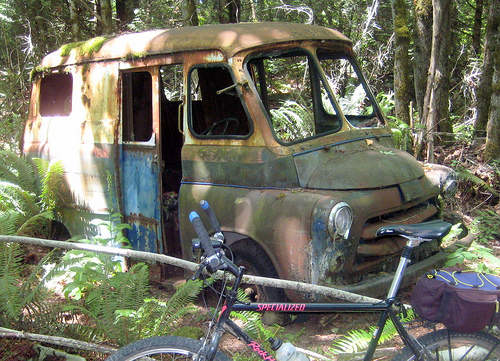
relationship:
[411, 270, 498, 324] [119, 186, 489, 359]
bag on back of bike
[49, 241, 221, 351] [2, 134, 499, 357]
plant on ground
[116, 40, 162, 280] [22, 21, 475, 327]
door on car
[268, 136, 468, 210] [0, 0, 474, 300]
hood on truck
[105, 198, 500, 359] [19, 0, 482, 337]
bicycle in front of truck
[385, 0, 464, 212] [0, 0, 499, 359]
tree in woods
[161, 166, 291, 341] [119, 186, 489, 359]
handle bars on bike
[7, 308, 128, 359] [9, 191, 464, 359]
branch on fence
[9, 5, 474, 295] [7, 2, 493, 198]
car in woods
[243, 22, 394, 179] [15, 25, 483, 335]
windshield of car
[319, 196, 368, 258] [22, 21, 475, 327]
head light of car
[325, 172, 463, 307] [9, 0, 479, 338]
grill of car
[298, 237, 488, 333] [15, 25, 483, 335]
bumper of car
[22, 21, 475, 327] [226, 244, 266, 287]
car has a wheel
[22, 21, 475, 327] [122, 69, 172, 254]
car has a door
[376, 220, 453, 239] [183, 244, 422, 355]
seat on bicycle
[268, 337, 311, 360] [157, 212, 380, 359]
bottle on bike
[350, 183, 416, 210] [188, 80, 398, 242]
area on car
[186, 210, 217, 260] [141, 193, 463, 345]
handle bars on bike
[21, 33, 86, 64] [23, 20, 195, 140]
moss on car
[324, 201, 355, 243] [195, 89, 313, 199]
head light on car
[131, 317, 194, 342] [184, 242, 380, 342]
tire on bike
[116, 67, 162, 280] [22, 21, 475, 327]
door on car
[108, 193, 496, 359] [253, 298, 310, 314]
bicycle with writing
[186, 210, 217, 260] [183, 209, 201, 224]
handle bars with end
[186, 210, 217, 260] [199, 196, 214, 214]
handle bars with end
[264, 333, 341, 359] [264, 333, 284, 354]
bottle with top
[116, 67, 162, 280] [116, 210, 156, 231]
door with rust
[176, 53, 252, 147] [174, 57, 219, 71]
window with rust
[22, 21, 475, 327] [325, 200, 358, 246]
car has headlight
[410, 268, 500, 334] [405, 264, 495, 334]
bag in bag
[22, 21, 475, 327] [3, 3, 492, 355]
car in woods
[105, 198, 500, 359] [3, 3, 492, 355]
bicycle in woods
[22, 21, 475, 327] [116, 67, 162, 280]
car has door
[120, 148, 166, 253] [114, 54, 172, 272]
paint on door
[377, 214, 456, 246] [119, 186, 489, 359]
seat of bike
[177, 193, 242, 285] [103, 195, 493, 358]
handlebars of bike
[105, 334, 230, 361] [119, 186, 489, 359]
tire of bike